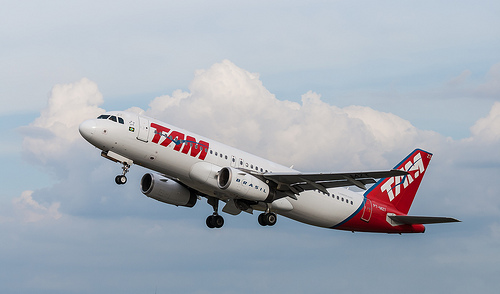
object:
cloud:
[1, 64, 498, 225]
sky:
[0, 1, 499, 292]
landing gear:
[206, 214, 226, 229]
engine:
[216, 167, 273, 204]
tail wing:
[388, 213, 464, 226]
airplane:
[78, 111, 460, 235]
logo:
[149, 123, 211, 161]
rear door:
[360, 199, 373, 222]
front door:
[136, 118, 149, 143]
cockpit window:
[97, 114, 111, 120]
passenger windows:
[350, 201, 354, 205]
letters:
[236, 178, 243, 183]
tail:
[364, 148, 434, 214]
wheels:
[114, 174, 128, 185]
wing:
[253, 170, 410, 202]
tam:
[380, 154, 425, 202]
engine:
[139, 174, 197, 208]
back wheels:
[205, 214, 231, 227]